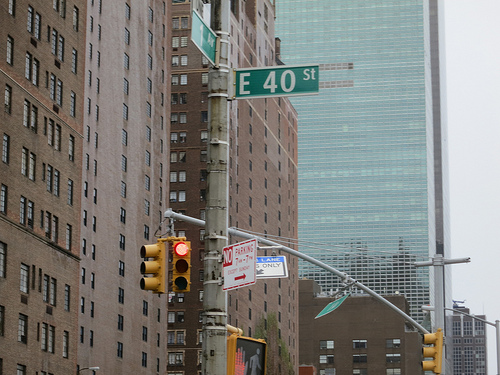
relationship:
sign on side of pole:
[231, 60, 323, 103] [197, 0, 233, 372]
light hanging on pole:
[172, 238, 191, 260] [161, 204, 445, 336]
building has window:
[2, 1, 91, 372] [69, 46, 80, 75]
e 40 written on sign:
[238, 68, 298, 96] [231, 60, 323, 103]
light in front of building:
[172, 238, 191, 260] [2, 1, 91, 372]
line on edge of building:
[422, 3, 440, 337] [274, 3, 455, 374]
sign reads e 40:
[231, 60, 323, 103] [238, 68, 298, 96]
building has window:
[274, 3, 455, 374] [373, 265, 382, 273]